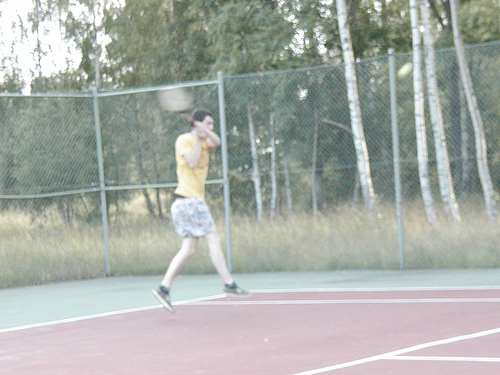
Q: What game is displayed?
A: Tennis.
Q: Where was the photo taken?
A: Tennis court.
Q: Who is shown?
A: Tennis player.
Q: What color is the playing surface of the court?
A: Red.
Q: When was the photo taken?
A: Daytime.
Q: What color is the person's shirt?
A: Yellow.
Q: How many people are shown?
A: One.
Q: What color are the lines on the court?
A: White.